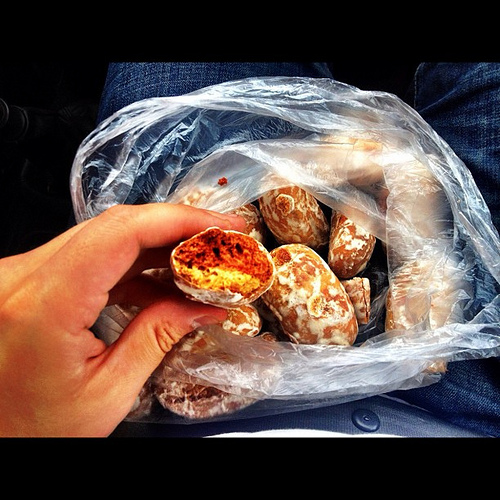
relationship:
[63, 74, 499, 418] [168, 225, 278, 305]
bag of bite-size snack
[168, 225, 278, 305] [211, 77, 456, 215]
bite-size snack in bag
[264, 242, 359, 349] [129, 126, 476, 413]
bite-size snack in bag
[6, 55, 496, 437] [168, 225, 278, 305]
person eating bite-size snack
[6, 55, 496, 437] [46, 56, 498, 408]
person wearing blue jeans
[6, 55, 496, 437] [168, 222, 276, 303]
person holding food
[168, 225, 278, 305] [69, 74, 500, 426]
bite-size snack in bag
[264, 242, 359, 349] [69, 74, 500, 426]
bite-size snack in bag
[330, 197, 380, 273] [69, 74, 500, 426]
bite-size snack in bag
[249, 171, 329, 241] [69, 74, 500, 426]
bite-size snack in bag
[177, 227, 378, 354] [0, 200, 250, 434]
food in hand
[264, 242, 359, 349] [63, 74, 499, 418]
bite-size snack in bag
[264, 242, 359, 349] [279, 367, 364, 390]
bite-size snack in bag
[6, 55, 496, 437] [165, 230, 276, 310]
person holding pastry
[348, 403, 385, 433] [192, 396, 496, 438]
button on seat belt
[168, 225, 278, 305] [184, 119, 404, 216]
bite-size snack in plastic bag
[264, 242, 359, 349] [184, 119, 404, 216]
bite-size snack in plastic bag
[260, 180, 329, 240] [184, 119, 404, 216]
bite-size snack in plastic bag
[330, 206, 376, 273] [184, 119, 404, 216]
bite-size snack in plastic bag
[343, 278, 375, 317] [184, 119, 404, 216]
pastry in plastic bag